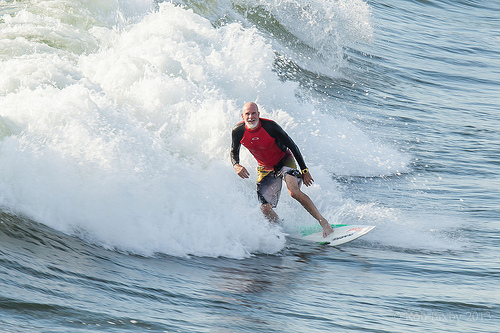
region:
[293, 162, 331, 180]
man wearing a yellow watch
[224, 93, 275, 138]
man has a beard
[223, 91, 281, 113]
man is bald at top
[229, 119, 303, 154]
surf shirt is black and red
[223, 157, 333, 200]
swimsuit is yellow, black and white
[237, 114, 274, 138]
man's beard is white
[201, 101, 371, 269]
man is surfing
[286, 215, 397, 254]
surfboard is green and white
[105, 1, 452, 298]
waves in the ocean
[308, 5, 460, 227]
spray from the wave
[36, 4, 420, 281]
a large wave crashing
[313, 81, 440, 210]
a spray of water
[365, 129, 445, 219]
a few water droplets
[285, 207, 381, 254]
a green and white surfboard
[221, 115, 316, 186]
a red and black rash guard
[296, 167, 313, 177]
a bright yellow watch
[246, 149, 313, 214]
a pair of boardshorts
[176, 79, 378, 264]
a man surfing a wave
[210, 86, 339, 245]
an old man soaking wet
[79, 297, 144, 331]
some bubbles in the water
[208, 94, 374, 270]
The man is surfing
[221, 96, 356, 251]
The man is standing on the board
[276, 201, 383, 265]
The board is blue and white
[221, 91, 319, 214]
The man is wearing a red and black shirt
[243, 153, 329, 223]
The man is wearing grey and yellow shorts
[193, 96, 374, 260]
The man is in front of the wave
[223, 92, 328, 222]
The man is looking at the camera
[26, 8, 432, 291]
The wave is breaking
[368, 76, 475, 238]
The water is dark blue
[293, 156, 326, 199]
The man is wearing a yellow watch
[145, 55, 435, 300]
A man in the ocean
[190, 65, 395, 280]
A man surfing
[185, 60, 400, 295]
A surfer riding a wave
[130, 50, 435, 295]
A man surfing in the ocean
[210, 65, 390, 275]
A man on a surfboard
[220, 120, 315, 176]
A red and black wetsuit top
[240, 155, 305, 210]
Grey surfboard shorts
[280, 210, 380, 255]
A green and white surfboard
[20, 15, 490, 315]
Waves crashing in the ocean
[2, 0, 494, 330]
A man in the ocean on a surfboard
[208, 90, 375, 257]
the man on the surfboard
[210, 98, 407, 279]
the man in the ocean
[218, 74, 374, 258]
the man is surfing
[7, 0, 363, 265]
the wave on the ocean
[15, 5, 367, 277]
the wave is foaming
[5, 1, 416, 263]
the wave is crashing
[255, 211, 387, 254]
the surfboard is white and green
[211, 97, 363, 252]
the man wearing a wet suit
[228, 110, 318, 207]
the wet suit is red and black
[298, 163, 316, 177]
the yellow watch on the wrist